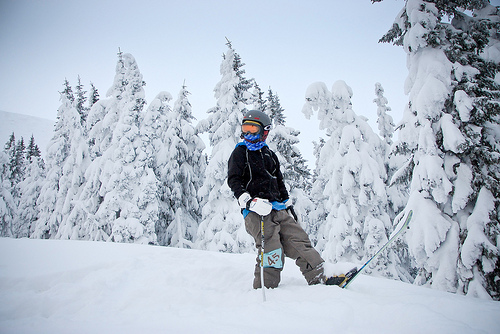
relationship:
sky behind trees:
[4, 1, 423, 156] [3, 2, 498, 291]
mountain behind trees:
[5, 112, 67, 152] [3, 2, 498, 291]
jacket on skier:
[223, 138, 341, 281] [226, 109, 346, 288]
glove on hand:
[238, 185, 281, 223] [232, 195, 282, 225]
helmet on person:
[234, 105, 274, 145] [225, 110, 349, 285]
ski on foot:
[330, 208, 411, 290] [311, 268, 348, 288]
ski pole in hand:
[256, 205, 267, 292] [248, 195, 273, 219]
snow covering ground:
[3, 11, 497, 325] [1, 231, 497, 330]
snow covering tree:
[3, 11, 497, 325] [369, 2, 499, 301]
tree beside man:
[369, 2, 499, 301] [225, 107, 357, 290]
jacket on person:
[223, 138, 341, 281] [225, 110, 349, 285]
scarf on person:
[232, 128, 278, 154] [211, 106, 385, 308]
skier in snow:
[226, 109, 346, 288] [3, 11, 497, 325]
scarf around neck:
[232, 128, 270, 151] [236, 136, 272, 147]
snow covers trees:
[3, 11, 497, 325] [9, 34, 484, 267]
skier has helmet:
[226, 109, 346, 288] [241, 108, 270, 143]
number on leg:
[266, 251, 281, 266] [244, 209, 284, 289]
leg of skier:
[244, 209, 284, 289] [226, 109, 346, 288]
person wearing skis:
[224, 109, 361, 288] [322, 210, 424, 286]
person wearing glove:
[224, 109, 361, 288] [244, 196, 279, 218]